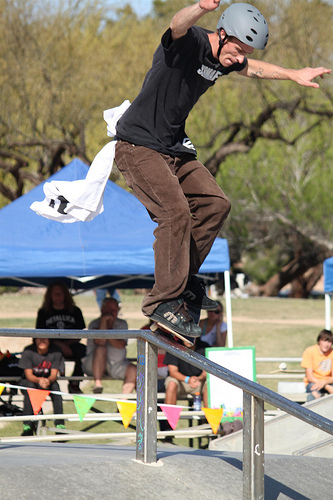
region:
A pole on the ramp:
[195, 347, 288, 429]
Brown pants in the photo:
[143, 169, 218, 247]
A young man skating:
[94, 26, 239, 268]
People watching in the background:
[29, 270, 190, 409]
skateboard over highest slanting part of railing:
[111, 270, 227, 372]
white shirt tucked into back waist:
[29, 95, 134, 226]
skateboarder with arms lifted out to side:
[143, 3, 329, 98]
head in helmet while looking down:
[217, 2, 268, 70]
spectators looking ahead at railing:
[8, 287, 224, 441]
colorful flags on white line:
[5, 380, 220, 435]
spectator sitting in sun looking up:
[293, 325, 331, 401]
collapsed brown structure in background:
[227, 152, 323, 297]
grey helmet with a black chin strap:
[214, 2, 268, 62]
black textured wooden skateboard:
[151, 298, 202, 348]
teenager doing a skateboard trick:
[114, 0, 331, 340]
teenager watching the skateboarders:
[300, 328, 331, 401]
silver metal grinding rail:
[0, 327, 332, 498]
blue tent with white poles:
[0, 153, 233, 346]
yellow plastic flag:
[201, 405, 224, 434]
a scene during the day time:
[6, 13, 326, 492]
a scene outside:
[10, 13, 326, 492]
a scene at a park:
[7, 4, 331, 497]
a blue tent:
[0, 142, 254, 351]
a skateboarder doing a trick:
[22, 3, 332, 372]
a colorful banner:
[8, 359, 246, 463]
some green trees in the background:
[4, 13, 332, 297]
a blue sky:
[7, 0, 294, 39]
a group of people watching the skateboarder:
[4, 252, 332, 443]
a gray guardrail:
[9, 316, 329, 497]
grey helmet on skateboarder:
[212, 0, 271, 69]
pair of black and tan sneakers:
[141, 277, 222, 339]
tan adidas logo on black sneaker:
[161, 307, 180, 326]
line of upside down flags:
[0, 375, 242, 439]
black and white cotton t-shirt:
[112, 21, 248, 161]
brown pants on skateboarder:
[108, 132, 235, 318]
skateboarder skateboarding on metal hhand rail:
[0, 1, 331, 437]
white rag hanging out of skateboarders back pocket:
[25, 95, 130, 226]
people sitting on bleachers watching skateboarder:
[17, 279, 229, 447]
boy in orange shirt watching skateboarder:
[295, 326, 332, 403]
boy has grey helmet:
[192, 6, 290, 61]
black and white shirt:
[166, 34, 234, 186]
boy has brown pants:
[86, 120, 239, 328]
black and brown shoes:
[117, 289, 235, 367]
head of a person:
[218, 5, 265, 66]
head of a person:
[314, 331, 329, 350]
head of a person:
[33, 334, 49, 349]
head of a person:
[102, 300, 120, 317]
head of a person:
[46, 281, 67, 305]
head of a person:
[205, 300, 222, 317]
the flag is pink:
[161, 406, 178, 427]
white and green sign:
[208, 346, 252, 421]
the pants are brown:
[115, 141, 234, 298]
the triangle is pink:
[158, 403, 181, 431]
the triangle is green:
[70, 390, 98, 425]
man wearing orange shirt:
[295, 326, 332, 404]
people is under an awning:
[3, 185, 238, 386]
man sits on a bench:
[84, 290, 139, 405]